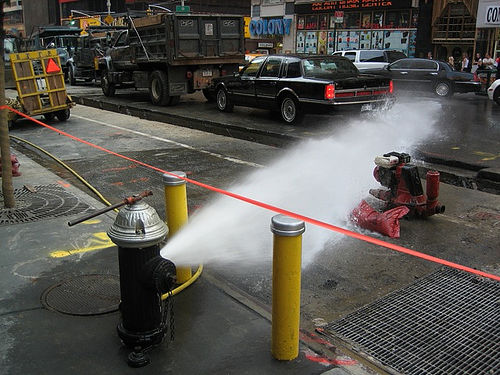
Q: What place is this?
A: It is a street.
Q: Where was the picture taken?
A: It was taken at the street.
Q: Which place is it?
A: It is a street.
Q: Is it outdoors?
A: Yes, it is outdoors.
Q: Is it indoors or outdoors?
A: It is outdoors.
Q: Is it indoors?
A: No, it is outdoors.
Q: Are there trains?
A: No, there are no trains.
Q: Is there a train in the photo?
A: No, there are no trains.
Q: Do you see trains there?
A: No, there are no trains.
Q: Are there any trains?
A: No, there are no trains.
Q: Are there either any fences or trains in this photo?
A: No, there are no trains or fences.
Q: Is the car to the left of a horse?
A: No, the car is to the left of a person.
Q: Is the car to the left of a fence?
A: No, the car is to the left of a person.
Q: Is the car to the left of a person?
A: Yes, the car is to the left of a person.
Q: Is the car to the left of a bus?
A: No, the car is to the left of a person.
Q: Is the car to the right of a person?
A: No, the car is to the left of a person.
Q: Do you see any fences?
A: No, there are no fences.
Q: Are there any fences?
A: No, there are no fences.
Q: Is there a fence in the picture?
A: No, there are no fences.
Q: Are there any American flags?
A: No, there are no American flags.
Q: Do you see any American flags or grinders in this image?
A: No, there are no American flags or grinders.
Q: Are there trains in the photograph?
A: No, there are no trains.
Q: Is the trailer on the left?
A: Yes, the trailer is on the left of the image.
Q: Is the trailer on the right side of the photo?
A: No, the trailer is on the left of the image.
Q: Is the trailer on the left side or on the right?
A: The trailer is on the left of the image.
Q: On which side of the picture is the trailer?
A: The trailer is on the left of the image.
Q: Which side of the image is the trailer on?
A: The trailer is on the left of the image.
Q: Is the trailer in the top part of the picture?
A: Yes, the trailer is in the top of the image.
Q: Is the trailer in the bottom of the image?
A: No, the trailer is in the top of the image.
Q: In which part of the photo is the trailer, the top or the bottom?
A: The trailer is in the top of the image.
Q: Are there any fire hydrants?
A: Yes, there is a fire hydrant.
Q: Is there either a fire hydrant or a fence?
A: Yes, there is a fire hydrant.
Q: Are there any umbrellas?
A: No, there are no umbrellas.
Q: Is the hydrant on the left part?
A: Yes, the hydrant is on the left of the image.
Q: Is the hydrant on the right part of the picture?
A: No, the hydrant is on the left of the image.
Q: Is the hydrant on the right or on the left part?
A: The hydrant is on the left of the image.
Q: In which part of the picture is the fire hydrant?
A: The fire hydrant is on the left of the image.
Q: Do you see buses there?
A: No, there are no buses.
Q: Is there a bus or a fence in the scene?
A: No, there are no buses or fences.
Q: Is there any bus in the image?
A: No, there are no buses.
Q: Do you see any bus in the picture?
A: No, there are no buses.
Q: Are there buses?
A: No, there are no buses.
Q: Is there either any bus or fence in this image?
A: No, there are no buses or fences.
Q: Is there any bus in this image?
A: No, there are no buses.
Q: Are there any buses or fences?
A: No, there are no buses or fences.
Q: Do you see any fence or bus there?
A: No, there are no buses or fences.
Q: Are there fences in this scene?
A: No, there are no fences.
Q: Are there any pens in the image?
A: No, there are no pens.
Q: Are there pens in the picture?
A: No, there are no pens.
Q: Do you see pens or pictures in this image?
A: No, there are no pens or pictures.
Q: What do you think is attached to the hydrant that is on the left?
A: The chain is attached to the fire hydrant.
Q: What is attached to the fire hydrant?
A: The chain is attached to the fire hydrant.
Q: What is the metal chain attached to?
A: The chain is attached to the fire hydrant.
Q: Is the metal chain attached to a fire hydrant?
A: Yes, the chain is attached to a fire hydrant.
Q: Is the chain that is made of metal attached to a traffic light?
A: No, the chain is attached to a fire hydrant.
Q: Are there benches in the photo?
A: No, there are no benches.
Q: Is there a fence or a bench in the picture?
A: No, there are no benches or fences.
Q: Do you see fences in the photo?
A: No, there are no fences.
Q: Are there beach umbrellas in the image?
A: No, there are no beach umbrellas.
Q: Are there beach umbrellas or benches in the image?
A: No, there are no beach umbrellas or benches.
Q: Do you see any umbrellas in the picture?
A: No, there are no umbrellas.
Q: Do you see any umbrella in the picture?
A: No, there are no umbrellas.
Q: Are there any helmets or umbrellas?
A: No, there are no umbrellas or helmets.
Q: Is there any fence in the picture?
A: No, there are no fences.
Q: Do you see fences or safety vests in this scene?
A: No, there are no fences or safety vests.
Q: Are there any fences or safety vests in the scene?
A: No, there are no fences or safety vests.